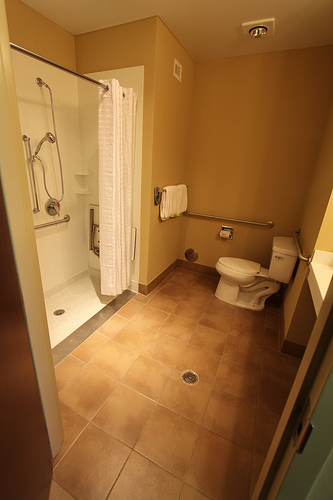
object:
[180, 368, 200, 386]
drain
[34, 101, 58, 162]
showerfaucet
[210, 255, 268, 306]
toilet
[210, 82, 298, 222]
wall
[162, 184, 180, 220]
bathtowels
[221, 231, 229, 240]
toiletpaper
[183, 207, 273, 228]
handle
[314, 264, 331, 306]
countertop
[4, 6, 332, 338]
bathroom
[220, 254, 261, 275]
closedlid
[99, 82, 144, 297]
curtain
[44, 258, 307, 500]
ceramicfloor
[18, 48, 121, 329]
shower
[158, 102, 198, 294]
wall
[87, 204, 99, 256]
chair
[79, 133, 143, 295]
showerwall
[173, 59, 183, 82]
airvent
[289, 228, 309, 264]
silvergrabbar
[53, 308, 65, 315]
drain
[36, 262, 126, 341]
showerfloor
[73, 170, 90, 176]
smallshelves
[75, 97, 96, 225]
corner of shower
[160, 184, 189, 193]
bar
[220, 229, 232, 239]
rollpaper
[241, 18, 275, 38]
lightfixture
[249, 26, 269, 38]
edging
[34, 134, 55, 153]
metal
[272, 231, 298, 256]
tankcover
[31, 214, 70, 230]
bathroomwallrail